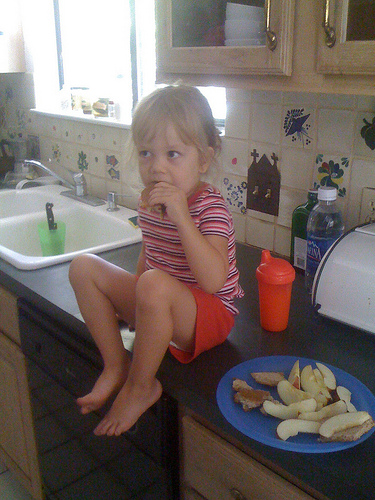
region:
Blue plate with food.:
[214, 348, 372, 459]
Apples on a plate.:
[215, 351, 371, 451]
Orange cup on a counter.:
[254, 246, 297, 333]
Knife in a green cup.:
[32, 200, 67, 260]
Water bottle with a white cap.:
[297, 182, 345, 296]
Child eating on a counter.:
[67, 84, 243, 437]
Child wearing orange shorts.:
[65, 83, 246, 440]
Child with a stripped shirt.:
[57, 85, 249, 435]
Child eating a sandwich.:
[66, 76, 246, 440]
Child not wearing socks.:
[62, 82, 240, 439]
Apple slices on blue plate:
[267, 355, 365, 433]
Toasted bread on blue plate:
[225, 360, 278, 407]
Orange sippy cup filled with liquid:
[251, 245, 296, 332]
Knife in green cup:
[33, 197, 63, 250]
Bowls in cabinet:
[217, 0, 264, 45]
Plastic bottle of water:
[300, 180, 337, 293]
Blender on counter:
[1, 135, 31, 180]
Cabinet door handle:
[315, 0, 334, 45]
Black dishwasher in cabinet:
[11, 300, 179, 497]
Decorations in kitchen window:
[60, 83, 121, 121]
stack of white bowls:
[222, 2, 272, 55]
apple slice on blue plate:
[244, 420, 300, 444]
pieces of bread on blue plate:
[232, 362, 283, 409]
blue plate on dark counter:
[214, 342, 374, 466]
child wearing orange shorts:
[174, 281, 236, 366]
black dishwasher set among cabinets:
[8, 311, 197, 499]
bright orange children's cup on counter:
[253, 243, 296, 338]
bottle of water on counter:
[305, 183, 344, 290]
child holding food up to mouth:
[133, 174, 178, 220]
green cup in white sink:
[36, 220, 71, 259]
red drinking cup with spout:
[247, 245, 302, 330]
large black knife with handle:
[37, 200, 61, 230]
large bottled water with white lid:
[307, 184, 342, 284]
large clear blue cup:
[37, 221, 71, 253]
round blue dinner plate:
[216, 348, 374, 461]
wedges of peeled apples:
[270, 373, 332, 418]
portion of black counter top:
[0, 267, 61, 305]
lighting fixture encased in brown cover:
[240, 142, 293, 230]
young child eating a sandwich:
[67, 83, 234, 449]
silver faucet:
[12, 143, 94, 200]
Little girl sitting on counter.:
[65, 85, 245, 439]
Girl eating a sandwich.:
[122, 166, 227, 229]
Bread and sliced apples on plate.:
[214, 352, 374, 460]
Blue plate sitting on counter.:
[214, 352, 368, 459]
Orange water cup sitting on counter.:
[254, 241, 297, 337]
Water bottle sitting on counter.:
[302, 182, 341, 310]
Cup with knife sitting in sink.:
[30, 195, 75, 255]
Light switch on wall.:
[240, 145, 291, 221]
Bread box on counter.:
[312, 223, 374, 338]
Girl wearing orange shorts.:
[135, 267, 236, 366]